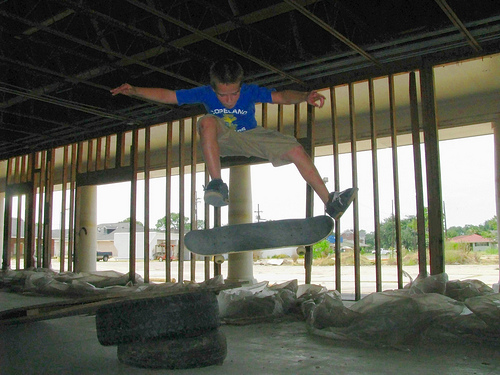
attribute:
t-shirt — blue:
[166, 77, 273, 132]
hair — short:
[202, 52, 274, 99]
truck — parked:
[60, 232, 137, 263]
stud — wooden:
[385, 73, 476, 304]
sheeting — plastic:
[5, 265, 499, 357]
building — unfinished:
[2, 5, 498, 372]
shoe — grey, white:
[323, 181, 360, 221]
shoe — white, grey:
[193, 180, 231, 205]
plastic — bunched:
[217, 270, 498, 351]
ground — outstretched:
[349, 110, 416, 176]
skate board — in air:
[177, 213, 347, 260]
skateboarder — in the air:
[108, 56, 358, 219]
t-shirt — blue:
[173, 81, 277, 128]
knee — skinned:
[195, 115, 215, 137]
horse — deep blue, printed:
[175, 82, 275, 138]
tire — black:
[92, 270, 202, 337]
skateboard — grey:
[191, 213, 328, 264]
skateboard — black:
[174, 215, 339, 260]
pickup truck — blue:
[92, 249, 114, 264]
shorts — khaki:
[187, 107, 292, 153]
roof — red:
[442, 215, 498, 265]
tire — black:
[113, 331, 229, 367]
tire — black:
[92, 296, 239, 341]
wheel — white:
[212, 252, 224, 263]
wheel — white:
[295, 247, 306, 256]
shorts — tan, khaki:
[197, 113, 302, 172]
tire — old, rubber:
[94, 290, 219, 345]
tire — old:
[117, 335, 225, 368]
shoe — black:
[202, 180, 228, 205]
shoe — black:
[325, 186, 357, 217]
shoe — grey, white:
[327, 186, 362, 216]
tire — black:
[92, 288, 226, 346]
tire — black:
[116, 327, 228, 372]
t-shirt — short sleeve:
[178, 85, 275, 130]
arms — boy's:
[105, 77, 331, 111]